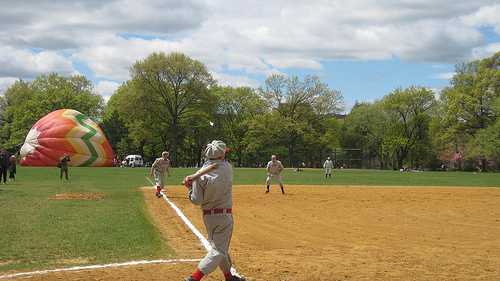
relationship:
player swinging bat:
[153, 130, 293, 277] [174, 164, 220, 180]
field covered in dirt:
[0, 163, 497, 279] [150, 182, 499, 277]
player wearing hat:
[178, 138, 248, 279] [204, 139, 232, 159]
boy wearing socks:
[169, 132, 275, 279] [181, 256, 238, 275]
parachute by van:
[12, 105, 126, 165] [119, 147, 147, 167]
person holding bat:
[174, 137, 244, 278] [193, 168, 226, 185]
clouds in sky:
[1, 5, 471, 74] [11, 6, 413, 74]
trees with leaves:
[0, 45, 499, 181] [183, 98, 211, 112]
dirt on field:
[2, 182, 498, 279] [0, 163, 497, 279]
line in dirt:
[155, 182, 210, 272] [181, 175, 498, 241]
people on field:
[151, 146, 169, 198] [104, 164, 494, 279]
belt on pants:
[199, 204, 232, 213] [197, 212, 237, 269]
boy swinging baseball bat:
[179, 139, 251, 281] [181, 162, 216, 187]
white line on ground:
[147, 177, 240, 279] [0, 161, 495, 276]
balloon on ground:
[18, 105, 115, 167] [0, 161, 495, 276]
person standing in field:
[254, 141, 294, 179] [19, 140, 424, 280]